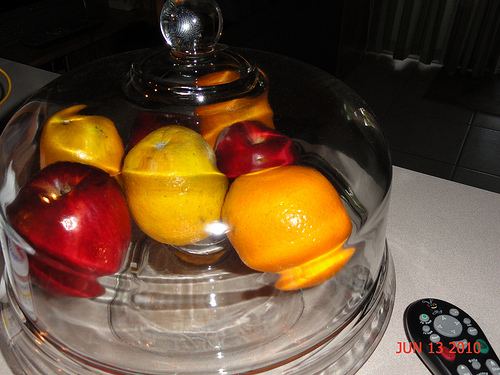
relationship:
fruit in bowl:
[228, 159, 355, 282] [4, 6, 405, 374]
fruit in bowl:
[6, 159, 138, 280] [4, 6, 405, 374]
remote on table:
[399, 292, 499, 374] [5, 56, 498, 358]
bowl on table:
[4, 6, 405, 374] [5, 56, 498, 358]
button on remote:
[433, 313, 465, 339] [399, 292, 499, 374]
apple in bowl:
[208, 120, 299, 174] [4, 6, 405, 374]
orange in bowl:
[120, 130, 228, 236] [4, 6, 405, 374]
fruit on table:
[228, 159, 355, 282] [5, 56, 498, 358]